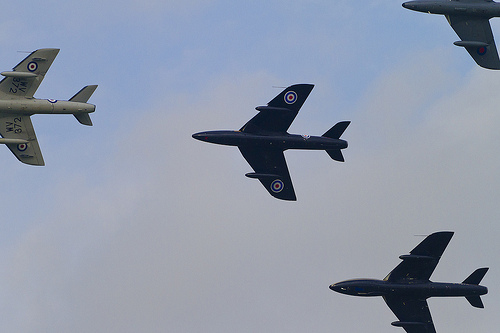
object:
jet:
[188, 82, 351, 202]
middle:
[149, 80, 371, 234]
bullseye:
[282, 89, 299, 106]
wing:
[236, 81, 319, 131]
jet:
[0, 70, 38, 146]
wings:
[1, 114, 50, 169]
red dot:
[25, 60, 39, 70]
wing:
[0, 45, 66, 100]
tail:
[318, 116, 356, 168]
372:
[9, 114, 26, 136]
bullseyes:
[269, 177, 284, 194]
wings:
[236, 149, 302, 204]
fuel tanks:
[238, 128, 289, 151]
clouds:
[381, 54, 446, 89]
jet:
[325, 229, 490, 332]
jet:
[0, 49, 99, 164]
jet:
[400, 0, 499, 72]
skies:
[1, 0, 498, 330]